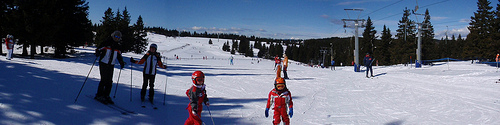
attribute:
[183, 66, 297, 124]
kids — skiing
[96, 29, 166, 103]
adults — skiing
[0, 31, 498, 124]
snow — white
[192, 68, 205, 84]
helmet — red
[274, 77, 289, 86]
helmet — red, orange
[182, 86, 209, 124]
snowsuit — red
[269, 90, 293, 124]
snowsuit — red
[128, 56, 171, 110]
poles — black, long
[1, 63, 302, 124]
shadow — large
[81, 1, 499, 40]
sky — blue, clear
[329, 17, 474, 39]
clouds — fluffy, white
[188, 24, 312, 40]
clouds — white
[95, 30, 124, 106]
parent — skiing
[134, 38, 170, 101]
parent — skiing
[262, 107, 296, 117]
gloves — blue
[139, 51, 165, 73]
coat — red, white, black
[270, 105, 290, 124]
pants — red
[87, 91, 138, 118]
skis — pair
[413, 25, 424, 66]
pole — large, gray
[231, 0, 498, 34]
lift — overhead